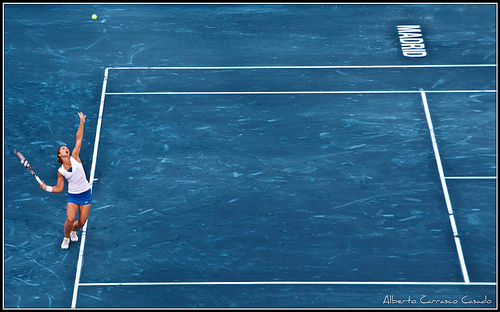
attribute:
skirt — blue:
[60, 191, 95, 203]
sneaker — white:
[70, 230, 80, 243]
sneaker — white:
[59, 235, 71, 248]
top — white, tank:
[55, 154, 90, 194]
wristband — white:
[38, 182, 59, 195]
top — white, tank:
[57, 158, 87, 189]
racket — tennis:
[13, 144, 47, 193]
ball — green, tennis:
[90, 12, 98, 25]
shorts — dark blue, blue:
[65, 187, 91, 204]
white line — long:
[75, 279, 498, 286]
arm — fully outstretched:
[70, 107, 87, 156]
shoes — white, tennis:
[59, 228, 79, 250]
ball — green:
[81, 14, 121, 45]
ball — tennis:
[87, 8, 106, 24]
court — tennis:
[27, 41, 483, 309]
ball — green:
[91, 10, 99, 19]